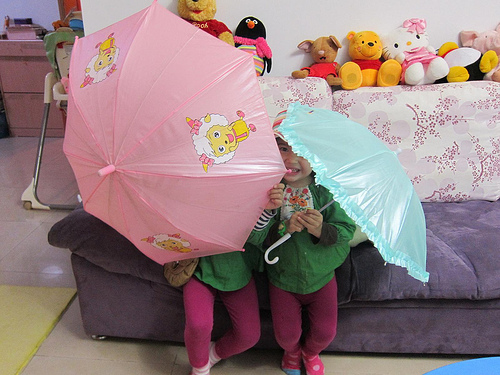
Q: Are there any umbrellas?
A: Yes, there is an umbrella.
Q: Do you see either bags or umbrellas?
A: Yes, there is an umbrella.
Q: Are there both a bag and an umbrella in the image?
A: No, there is an umbrella but no bags.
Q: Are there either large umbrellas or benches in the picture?
A: Yes, there is a large umbrella.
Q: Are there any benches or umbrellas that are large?
A: Yes, the umbrella is large.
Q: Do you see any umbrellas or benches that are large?
A: Yes, the umbrella is large.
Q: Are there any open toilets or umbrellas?
A: Yes, there is an open umbrella.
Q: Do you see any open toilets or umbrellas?
A: Yes, there is an open umbrella.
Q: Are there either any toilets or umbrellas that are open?
A: Yes, the umbrella is open.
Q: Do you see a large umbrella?
A: Yes, there is a large umbrella.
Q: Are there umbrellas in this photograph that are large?
A: Yes, there is an umbrella that is large.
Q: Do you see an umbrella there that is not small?
A: Yes, there is a large umbrella.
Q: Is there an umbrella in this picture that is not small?
A: Yes, there is a large umbrella.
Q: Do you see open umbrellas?
A: Yes, there is an open umbrella.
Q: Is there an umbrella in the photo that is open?
A: Yes, there is an umbrella that is open.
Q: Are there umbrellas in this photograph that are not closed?
A: Yes, there is a open umbrella.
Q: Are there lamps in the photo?
A: No, there are no lamps.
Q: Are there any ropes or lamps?
A: No, there are no lamps or ropes.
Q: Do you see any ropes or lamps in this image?
A: No, there are no lamps or ropes.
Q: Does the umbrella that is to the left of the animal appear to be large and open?
A: Yes, the umbrella is large and open.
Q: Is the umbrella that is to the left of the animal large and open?
A: Yes, the umbrella is large and open.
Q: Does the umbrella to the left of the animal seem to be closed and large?
A: No, the umbrella is large but open.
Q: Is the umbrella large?
A: Yes, the umbrella is large.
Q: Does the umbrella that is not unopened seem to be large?
A: Yes, the umbrella is large.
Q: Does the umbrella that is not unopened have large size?
A: Yes, the umbrella is large.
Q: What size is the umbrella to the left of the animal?
A: The umbrella is large.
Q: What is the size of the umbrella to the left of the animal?
A: The umbrella is large.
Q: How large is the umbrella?
A: The umbrella is large.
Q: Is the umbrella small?
A: No, the umbrella is large.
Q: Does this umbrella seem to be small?
A: No, the umbrella is large.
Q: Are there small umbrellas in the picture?
A: No, there is an umbrella but it is large.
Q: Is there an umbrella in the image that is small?
A: No, there is an umbrella but it is large.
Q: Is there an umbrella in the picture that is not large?
A: No, there is an umbrella but it is large.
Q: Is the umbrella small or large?
A: The umbrella is large.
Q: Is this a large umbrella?
A: Yes, this is a large umbrella.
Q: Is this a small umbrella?
A: No, this is a large umbrella.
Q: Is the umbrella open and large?
A: Yes, the umbrella is open and large.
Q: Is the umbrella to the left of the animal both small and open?
A: No, the umbrella is open but large.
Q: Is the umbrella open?
A: Yes, the umbrella is open.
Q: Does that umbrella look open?
A: Yes, the umbrella is open.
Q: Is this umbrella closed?
A: No, the umbrella is open.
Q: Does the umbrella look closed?
A: No, the umbrella is open.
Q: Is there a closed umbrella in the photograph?
A: No, there is an umbrella but it is open.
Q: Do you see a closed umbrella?
A: No, there is an umbrella but it is open.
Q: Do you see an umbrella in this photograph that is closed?
A: No, there is an umbrella but it is open.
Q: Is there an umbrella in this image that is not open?
A: No, there is an umbrella but it is open.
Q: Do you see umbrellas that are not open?
A: No, there is an umbrella but it is open.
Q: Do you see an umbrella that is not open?
A: No, there is an umbrella but it is open.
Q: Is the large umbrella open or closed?
A: The umbrella is open.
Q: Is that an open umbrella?
A: Yes, that is an open umbrella.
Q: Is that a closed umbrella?
A: No, that is an open umbrella.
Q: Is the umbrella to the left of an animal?
A: Yes, the umbrella is to the left of an animal.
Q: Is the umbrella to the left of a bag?
A: No, the umbrella is to the left of an animal.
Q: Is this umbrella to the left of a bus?
A: No, the umbrella is to the left of an animal.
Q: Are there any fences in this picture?
A: No, there are no fences.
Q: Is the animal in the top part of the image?
A: Yes, the animal is in the top of the image.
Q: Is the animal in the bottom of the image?
A: No, the animal is in the top of the image.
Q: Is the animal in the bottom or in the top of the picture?
A: The animal is in the top of the image.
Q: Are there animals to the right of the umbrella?
A: Yes, there is an animal to the right of the umbrella.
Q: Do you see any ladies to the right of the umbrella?
A: No, there is an animal to the right of the umbrella.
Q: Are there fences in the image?
A: No, there are no fences.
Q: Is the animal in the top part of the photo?
A: Yes, the animal is in the top of the image.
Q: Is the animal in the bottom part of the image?
A: No, the animal is in the top of the image.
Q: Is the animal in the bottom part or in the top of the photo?
A: The animal is in the top of the image.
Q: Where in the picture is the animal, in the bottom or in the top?
A: The animal is in the top of the image.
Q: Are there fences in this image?
A: No, there are no fences.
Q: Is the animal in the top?
A: Yes, the animal is in the top of the image.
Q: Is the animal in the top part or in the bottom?
A: The animal is in the top of the image.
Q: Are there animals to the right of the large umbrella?
A: Yes, there is an animal to the right of the umbrella.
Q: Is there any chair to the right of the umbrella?
A: No, there is an animal to the right of the umbrella.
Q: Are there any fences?
A: No, there are no fences.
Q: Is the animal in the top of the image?
A: Yes, the animal is in the top of the image.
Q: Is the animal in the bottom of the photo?
A: No, the animal is in the top of the image.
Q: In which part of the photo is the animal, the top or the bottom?
A: The animal is in the top of the image.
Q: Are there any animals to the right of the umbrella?
A: Yes, there is an animal to the right of the umbrella.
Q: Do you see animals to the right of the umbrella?
A: Yes, there is an animal to the right of the umbrella.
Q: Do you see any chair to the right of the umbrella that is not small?
A: No, there is an animal to the right of the umbrella.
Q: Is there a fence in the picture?
A: No, there are no fences.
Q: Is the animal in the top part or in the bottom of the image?
A: The animal is in the top of the image.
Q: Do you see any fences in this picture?
A: No, there are no fences.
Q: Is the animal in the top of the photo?
A: Yes, the animal is in the top of the image.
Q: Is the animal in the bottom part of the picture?
A: No, the animal is in the top of the image.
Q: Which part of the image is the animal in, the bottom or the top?
A: The animal is in the top of the image.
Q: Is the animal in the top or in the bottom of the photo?
A: The animal is in the top of the image.